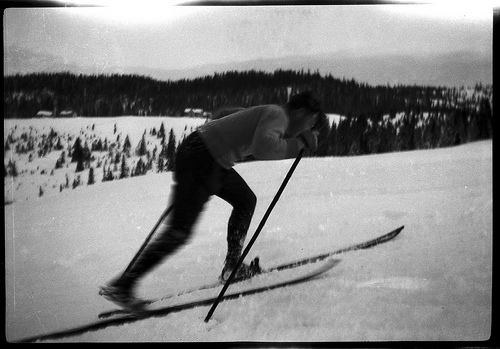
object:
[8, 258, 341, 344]
skies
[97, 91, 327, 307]
man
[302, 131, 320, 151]
glove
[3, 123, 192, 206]
trees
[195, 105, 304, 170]
sweater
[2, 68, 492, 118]
mountains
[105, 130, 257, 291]
black pants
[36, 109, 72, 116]
building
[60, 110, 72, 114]
snow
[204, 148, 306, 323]
ski pole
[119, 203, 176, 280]
ski pole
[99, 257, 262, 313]
ski boot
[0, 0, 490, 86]
clouds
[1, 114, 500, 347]
ground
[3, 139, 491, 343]
uphill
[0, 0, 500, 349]
photograph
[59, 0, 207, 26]
sun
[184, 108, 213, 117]
building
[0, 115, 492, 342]
hill